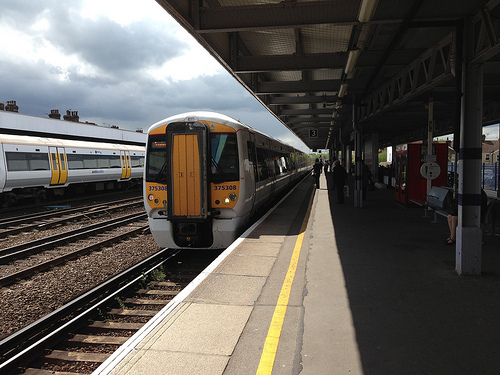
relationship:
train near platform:
[139, 125, 320, 239] [202, 2, 460, 359]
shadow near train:
[243, 172, 323, 232] [139, 125, 320, 239]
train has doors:
[139, 125, 320, 239] [166, 118, 204, 221]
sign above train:
[299, 122, 316, 141] [139, 125, 320, 239]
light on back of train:
[214, 195, 233, 213] [139, 125, 320, 239]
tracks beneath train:
[10, 255, 165, 357] [139, 125, 320, 239]